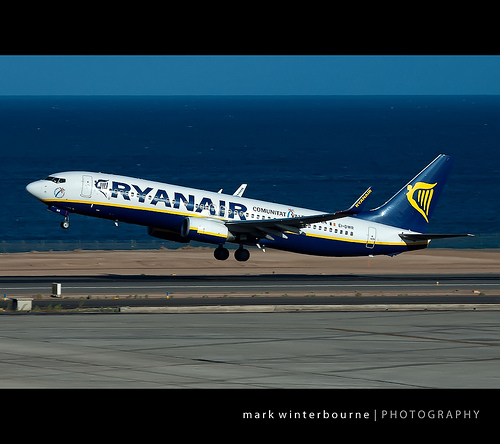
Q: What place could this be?
A: It is an ocean.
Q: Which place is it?
A: It is an ocean.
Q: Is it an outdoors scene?
A: Yes, it is outdoors.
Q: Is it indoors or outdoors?
A: It is outdoors.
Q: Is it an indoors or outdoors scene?
A: It is outdoors.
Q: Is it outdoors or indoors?
A: It is outdoors.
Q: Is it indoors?
A: No, it is outdoors.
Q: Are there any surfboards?
A: No, there are no surfboards.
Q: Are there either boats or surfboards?
A: No, there are no surfboards or boats.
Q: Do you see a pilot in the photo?
A: No, there are no pilots.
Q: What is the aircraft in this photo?
A: The aircraft is a jet.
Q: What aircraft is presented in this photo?
A: The aircraft is a jet.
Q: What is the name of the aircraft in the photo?
A: The aircraft is a jet.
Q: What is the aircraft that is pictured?
A: The aircraft is a jet.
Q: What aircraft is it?
A: The aircraft is a jet.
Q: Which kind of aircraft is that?
A: This is a jet.